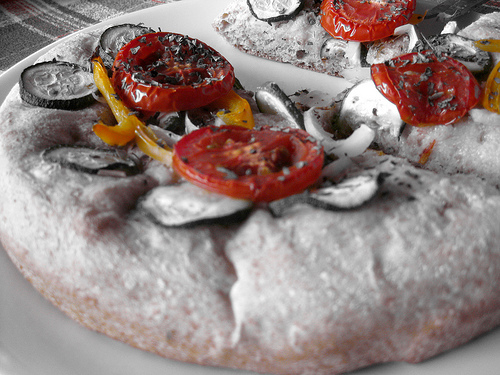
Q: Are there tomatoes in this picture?
A: Yes, there is a tomato.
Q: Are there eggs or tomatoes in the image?
A: Yes, there is a tomato.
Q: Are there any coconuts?
A: No, there are no coconuts.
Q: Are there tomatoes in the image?
A: Yes, there is a tomato.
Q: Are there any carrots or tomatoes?
A: Yes, there is a tomato.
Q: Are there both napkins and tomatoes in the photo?
A: No, there is a tomato but no napkins.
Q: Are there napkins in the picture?
A: No, there are no napkins.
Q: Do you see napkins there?
A: No, there are no napkins.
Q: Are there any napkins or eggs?
A: No, there are no napkins or eggs.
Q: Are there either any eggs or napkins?
A: No, there are no napkins or eggs.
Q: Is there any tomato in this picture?
A: Yes, there is a tomato.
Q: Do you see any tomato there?
A: Yes, there is a tomato.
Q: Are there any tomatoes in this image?
A: Yes, there is a tomato.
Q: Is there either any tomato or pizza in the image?
A: Yes, there is a tomato.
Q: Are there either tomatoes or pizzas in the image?
A: Yes, there is a tomato.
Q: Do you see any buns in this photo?
A: No, there are no buns.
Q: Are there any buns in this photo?
A: No, there are no buns.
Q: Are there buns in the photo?
A: No, there are no buns.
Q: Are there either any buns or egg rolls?
A: No, there are no buns or egg rolls.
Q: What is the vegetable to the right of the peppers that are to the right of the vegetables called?
A: The vegetable is a tomato.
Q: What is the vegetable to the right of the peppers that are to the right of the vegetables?
A: The vegetable is a tomato.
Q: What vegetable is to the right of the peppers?
A: The vegetable is a tomato.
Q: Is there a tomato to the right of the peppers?
A: Yes, there is a tomato to the right of the peppers.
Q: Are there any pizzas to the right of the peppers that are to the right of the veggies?
A: No, there is a tomato to the right of the peppers.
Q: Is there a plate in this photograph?
A: Yes, there is a plate.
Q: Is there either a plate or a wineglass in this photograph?
A: Yes, there is a plate.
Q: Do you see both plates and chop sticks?
A: No, there is a plate but no chopsticks.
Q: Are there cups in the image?
A: No, there are no cups.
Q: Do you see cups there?
A: No, there are no cups.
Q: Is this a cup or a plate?
A: This is a plate.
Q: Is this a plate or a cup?
A: This is a plate.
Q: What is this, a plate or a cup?
A: This is a plate.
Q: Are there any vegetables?
A: Yes, there are vegetables.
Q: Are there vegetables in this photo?
A: Yes, there are vegetables.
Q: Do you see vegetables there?
A: Yes, there are vegetables.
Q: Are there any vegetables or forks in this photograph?
A: Yes, there are vegetables.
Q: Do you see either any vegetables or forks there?
A: Yes, there are vegetables.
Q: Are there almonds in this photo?
A: No, there are no almonds.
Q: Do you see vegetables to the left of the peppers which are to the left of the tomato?
A: Yes, there are vegetables to the left of the peppers.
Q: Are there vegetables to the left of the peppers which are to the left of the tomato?
A: Yes, there are vegetables to the left of the peppers.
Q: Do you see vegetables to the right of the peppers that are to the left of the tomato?
A: No, the vegetables are to the left of the peppers.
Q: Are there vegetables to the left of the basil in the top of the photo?
A: Yes, there are vegetables to the left of the basil.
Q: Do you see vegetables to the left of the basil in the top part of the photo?
A: Yes, there are vegetables to the left of the basil.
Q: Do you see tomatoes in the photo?
A: Yes, there is a tomato.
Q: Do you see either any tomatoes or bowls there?
A: Yes, there is a tomato.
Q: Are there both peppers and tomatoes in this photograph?
A: Yes, there are both a tomato and a pepper.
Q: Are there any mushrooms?
A: No, there are no mushrooms.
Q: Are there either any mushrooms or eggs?
A: No, there are no mushrooms or eggs.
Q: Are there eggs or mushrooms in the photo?
A: No, there are no mushrooms or eggs.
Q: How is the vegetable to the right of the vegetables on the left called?
A: The vegetable is a tomato.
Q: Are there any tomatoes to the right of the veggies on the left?
A: Yes, there is a tomato to the right of the vegetables.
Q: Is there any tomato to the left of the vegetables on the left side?
A: No, the tomato is to the right of the vegetables.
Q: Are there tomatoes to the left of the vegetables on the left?
A: No, the tomato is to the right of the vegetables.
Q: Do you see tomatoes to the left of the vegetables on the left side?
A: No, the tomato is to the right of the vegetables.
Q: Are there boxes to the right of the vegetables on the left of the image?
A: No, there is a tomato to the right of the veggies.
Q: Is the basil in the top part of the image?
A: Yes, the basil is in the top of the image.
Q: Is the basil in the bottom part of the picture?
A: No, the basil is in the top of the image.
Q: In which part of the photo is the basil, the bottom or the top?
A: The basil is in the top of the image.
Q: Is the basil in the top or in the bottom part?
A: The basil is in the top of the image.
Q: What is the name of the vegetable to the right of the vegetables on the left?
A: The vegetable is basil.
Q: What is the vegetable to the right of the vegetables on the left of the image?
A: The vegetable is basil.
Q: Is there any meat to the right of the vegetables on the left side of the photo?
A: No, there is basil to the right of the vegetables.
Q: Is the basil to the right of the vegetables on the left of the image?
A: Yes, the basil is to the right of the vegetables.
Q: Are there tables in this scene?
A: Yes, there is a table.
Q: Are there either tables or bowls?
A: Yes, there is a table.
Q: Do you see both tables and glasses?
A: No, there is a table but no glasses.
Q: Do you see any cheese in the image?
A: No, there is no cheese.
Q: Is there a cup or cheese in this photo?
A: No, there are no cheese or cups.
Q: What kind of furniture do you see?
A: The furniture is a table.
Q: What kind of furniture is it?
A: The piece of furniture is a table.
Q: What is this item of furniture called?
A: This is a table.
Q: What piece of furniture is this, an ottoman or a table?
A: This is a table.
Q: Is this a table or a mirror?
A: This is a table.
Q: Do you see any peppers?
A: Yes, there are peppers.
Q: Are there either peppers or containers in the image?
A: Yes, there are peppers.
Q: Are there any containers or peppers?
A: Yes, there are peppers.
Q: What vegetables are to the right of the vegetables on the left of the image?
A: The vegetables are peppers.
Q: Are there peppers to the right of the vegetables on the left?
A: Yes, there are peppers to the right of the veggies.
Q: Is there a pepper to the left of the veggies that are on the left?
A: No, the peppers are to the right of the veggies.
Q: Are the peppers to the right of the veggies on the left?
A: Yes, the peppers are to the right of the vegetables.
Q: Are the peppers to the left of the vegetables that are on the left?
A: No, the peppers are to the right of the veggies.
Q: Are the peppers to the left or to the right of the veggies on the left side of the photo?
A: The peppers are to the right of the veggies.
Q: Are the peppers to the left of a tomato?
A: Yes, the peppers are to the left of a tomato.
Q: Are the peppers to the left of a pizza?
A: No, the peppers are to the left of a tomato.